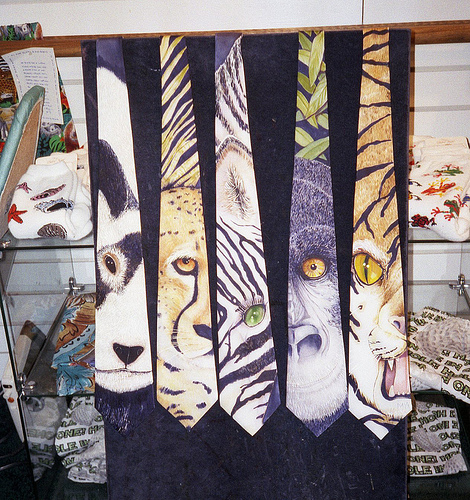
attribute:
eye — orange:
[300, 252, 328, 279]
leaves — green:
[293, 30, 329, 160]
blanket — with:
[1, 60, 92, 240]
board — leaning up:
[0, 85, 46, 217]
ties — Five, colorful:
[95, 31, 413, 438]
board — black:
[78, 27, 418, 498]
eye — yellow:
[350, 243, 389, 295]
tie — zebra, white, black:
[192, 41, 291, 463]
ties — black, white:
[78, 59, 433, 330]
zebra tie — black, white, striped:
[206, 38, 285, 446]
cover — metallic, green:
[0, 84, 46, 198]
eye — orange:
[175, 257, 195, 271]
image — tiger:
[341, 196, 410, 395]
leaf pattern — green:
[292, 26, 331, 166]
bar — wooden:
[0, 20, 467, 219]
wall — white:
[0, 0, 468, 495]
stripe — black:
[168, 145, 197, 173]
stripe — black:
[160, 86, 196, 134]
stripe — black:
[159, 50, 189, 95]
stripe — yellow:
[162, 38, 185, 78]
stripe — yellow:
[177, 173, 196, 187]